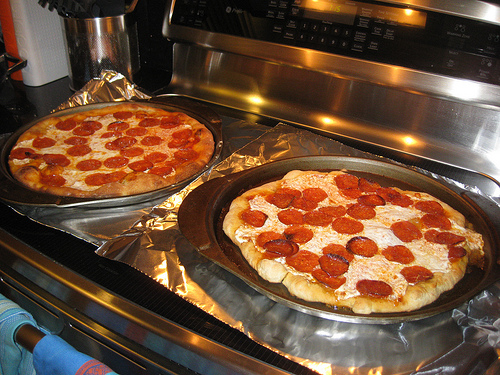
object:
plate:
[0, 101, 223, 212]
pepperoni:
[289, 187, 329, 210]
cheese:
[368, 222, 388, 235]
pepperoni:
[282, 225, 314, 245]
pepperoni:
[261, 236, 299, 259]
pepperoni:
[446, 245, 467, 268]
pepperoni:
[356, 193, 384, 208]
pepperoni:
[388, 219, 423, 243]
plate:
[178, 154, 500, 325]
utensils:
[37, 0, 127, 18]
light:
[397, 133, 430, 152]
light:
[399, 8, 414, 22]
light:
[242, 92, 267, 113]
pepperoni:
[285, 249, 320, 273]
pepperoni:
[317, 253, 349, 275]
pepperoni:
[324, 200, 347, 218]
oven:
[0, 225, 217, 372]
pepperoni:
[413, 199, 447, 215]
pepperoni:
[263, 188, 292, 209]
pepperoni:
[334, 172, 361, 190]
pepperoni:
[422, 228, 465, 247]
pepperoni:
[345, 236, 379, 257]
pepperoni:
[399, 264, 435, 284]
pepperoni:
[354, 278, 392, 299]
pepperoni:
[238, 208, 270, 228]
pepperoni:
[103, 154, 130, 169]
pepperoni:
[344, 203, 377, 220]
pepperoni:
[43, 172, 67, 188]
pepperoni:
[277, 208, 307, 224]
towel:
[58, 345, 74, 375]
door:
[0, 266, 194, 375]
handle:
[0, 294, 120, 375]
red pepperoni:
[330, 215, 363, 234]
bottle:
[13, 322, 103, 374]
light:
[308, 112, 339, 129]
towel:
[38, 340, 49, 372]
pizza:
[222, 168, 485, 315]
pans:
[177, 154, 500, 325]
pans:
[0, 101, 223, 211]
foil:
[93, 120, 499, 375]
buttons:
[162, 24, 500, 177]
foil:
[0, 68, 273, 249]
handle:
[0, 49, 28, 86]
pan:
[0, 30, 38, 127]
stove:
[0, 92, 500, 375]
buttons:
[269, 0, 402, 58]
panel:
[167, 0, 500, 85]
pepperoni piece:
[357, 176, 382, 194]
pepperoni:
[264, 186, 300, 210]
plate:
[177, 179, 238, 270]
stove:
[148, 0, 500, 204]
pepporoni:
[256, 230, 281, 247]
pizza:
[7, 102, 215, 200]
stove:
[0, 0, 499, 375]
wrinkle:
[140, 227, 181, 290]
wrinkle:
[270, 131, 311, 152]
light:
[314, 311, 362, 345]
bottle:
[56, 0, 142, 93]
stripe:
[1, 299, 14, 323]